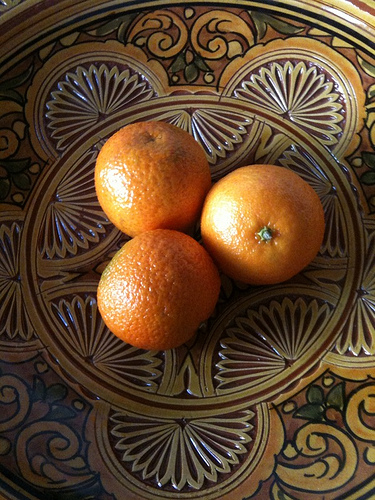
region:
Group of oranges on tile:
[94, 120, 330, 346]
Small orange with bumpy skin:
[93, 221, 216, 347]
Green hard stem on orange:
[258, 224, 270, 241]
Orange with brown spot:
[92, 119, 210, 234]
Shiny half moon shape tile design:
[88, 399, 289, 498]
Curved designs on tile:
[133, 4, 255, 87]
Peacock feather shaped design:
[111, 408, 257, 486]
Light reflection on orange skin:
[213, 197, 246, 240]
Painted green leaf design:
[297, 383, 348, 424]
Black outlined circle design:
[282, 401, 297, 412]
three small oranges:
[93, 135, 315, 335]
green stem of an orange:
[251, 219, 276, 252]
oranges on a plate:
[79, 116, 326, 362]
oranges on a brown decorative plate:
[77, 106, 345, 367]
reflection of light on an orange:
[97, 153, 139, 221]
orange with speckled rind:
[99, 223, 220, 355]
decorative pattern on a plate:
[13, 415, 110, 494]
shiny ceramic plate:
[46, 63, 108, 118]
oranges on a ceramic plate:
[87, 125, 329, 350]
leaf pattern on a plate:
[294, 366, 350, 430]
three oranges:
[33, 78, 341, 403]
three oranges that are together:
[43, 97, 367, 417]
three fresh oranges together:
[70, 89, 373, 397]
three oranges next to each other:
[38, 70, 374, 380]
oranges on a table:
[54, 98, 372, 413]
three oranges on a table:
[41, 36, 374, 458]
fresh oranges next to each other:
[59, 60, 364, 429]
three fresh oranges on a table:
[35, 110, 335, 386]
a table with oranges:
[37, 48, 367, 419]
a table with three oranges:
[57, 83, 371, 414]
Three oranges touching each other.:
[88, 109, 330, 353]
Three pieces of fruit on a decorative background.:
[90, 115, 332, 353]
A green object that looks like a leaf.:
[290, 381, 349, 431]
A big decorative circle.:
[15, 89, 366, 420]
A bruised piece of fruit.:
[92, 119, 213, 242]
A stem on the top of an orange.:
[257, 221, 273, 249]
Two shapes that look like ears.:
[30, 45, 357, 171]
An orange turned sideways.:
[94, 225, 224, 355]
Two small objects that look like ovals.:
[278, 373, 342, 415]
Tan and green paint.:
[127, 7, 256, 87]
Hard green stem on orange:
[259, 223, 272, 241]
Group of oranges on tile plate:
[71, 120, 324, 348]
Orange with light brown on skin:
[94, 126, 210, 234]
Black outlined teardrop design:
[182, 6, 195, 18]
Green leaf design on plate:
[296, 383, 346, 422]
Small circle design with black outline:
[279, 398, 295, 413]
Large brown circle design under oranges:
[20, 94, 366, 418]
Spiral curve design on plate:
[280, 421, 359, 492]